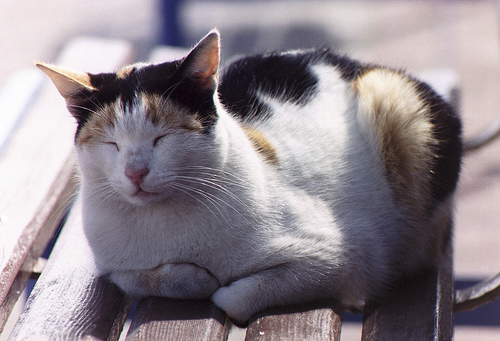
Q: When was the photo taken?
A: Daytime.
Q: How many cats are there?
A: One.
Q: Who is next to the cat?
A: No one.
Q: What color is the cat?
A: White, orange and black.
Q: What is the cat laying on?
A: A bench.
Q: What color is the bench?
A: Brown.